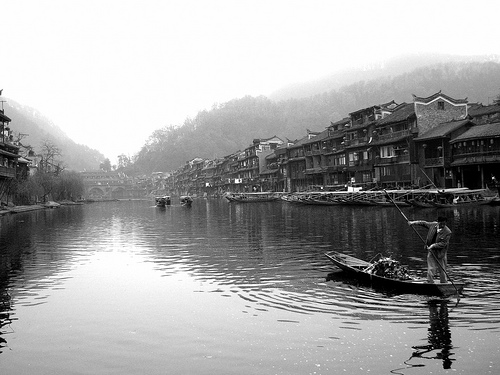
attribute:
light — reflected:
[91, 219, 147, 260]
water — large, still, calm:
[95, 230, 160, 250]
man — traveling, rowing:
[388, 203, 472, 284]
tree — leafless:
[36, 130, 62, 184]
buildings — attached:
[163, 81, 490, 211]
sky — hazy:
[71, 11, 248, 140]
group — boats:
[212, 149, 453, 221]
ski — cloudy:
[82, 73, 230, 157]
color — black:
[354, 256, 428, 297]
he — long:
[383, 171, 476, 299]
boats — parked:
[138, 152, 415, 216]